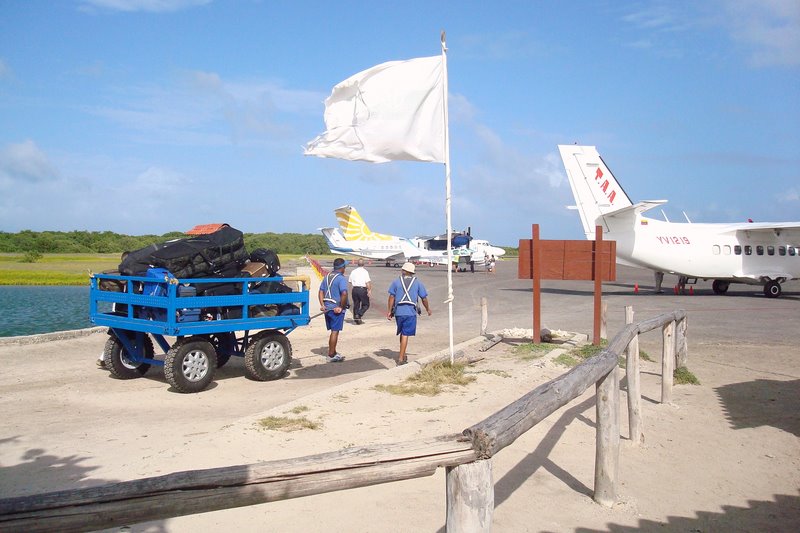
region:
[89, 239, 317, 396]
large blue cart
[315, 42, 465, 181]
white flag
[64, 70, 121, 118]
white clouds in blue sky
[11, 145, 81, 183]
white clouds in blue sky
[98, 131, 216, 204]
white clouds in blue sky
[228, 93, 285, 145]
white clouds in blue sky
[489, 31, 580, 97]
white clouds in blue sky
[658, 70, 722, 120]
white clouds in blue sky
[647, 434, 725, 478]
the sand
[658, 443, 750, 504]
the sand is light brown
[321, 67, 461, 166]
a flag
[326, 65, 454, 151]
the flag is white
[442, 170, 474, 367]
a pole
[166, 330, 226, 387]
the back wheel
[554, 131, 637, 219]
tail of the airplane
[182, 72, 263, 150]
the clouds are white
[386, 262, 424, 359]
a man standing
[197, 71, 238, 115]
white clouds in blue sky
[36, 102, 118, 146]
white clouds in blue sky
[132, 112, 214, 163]
white clouds in blue sky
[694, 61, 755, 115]
white clouds in blue sky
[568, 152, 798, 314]
old white plane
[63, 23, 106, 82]
white clouds in blue sky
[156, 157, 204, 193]
white clouds in blue sky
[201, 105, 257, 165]
white clouds in blue sky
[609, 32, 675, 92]
white clouds in blue sky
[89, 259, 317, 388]
large blue cart on wheels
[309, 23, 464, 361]
white flag blowing in the wind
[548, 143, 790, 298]
white airplane on the pavement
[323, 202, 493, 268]
plane in the distance in front of the men walking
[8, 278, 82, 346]
pond behind the blue cart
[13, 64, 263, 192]
pale clouds in the blue sky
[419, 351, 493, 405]
small patch of grass by the flag pole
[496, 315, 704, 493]
wooden fence near the flag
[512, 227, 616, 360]
back of a large brown sign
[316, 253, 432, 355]
two men in blue shirts and shorts